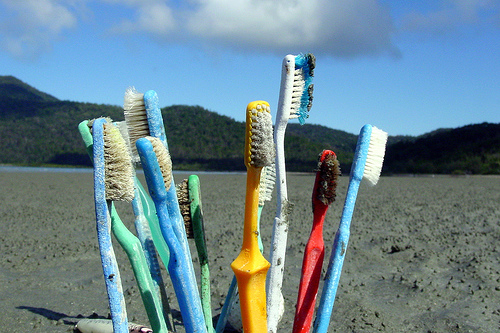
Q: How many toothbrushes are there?
A: Ten.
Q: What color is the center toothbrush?
A: Yellow.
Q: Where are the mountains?
A: The background.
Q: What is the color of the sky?
A: Blue.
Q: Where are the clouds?
A: The sky.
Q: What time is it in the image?
A: Daytime.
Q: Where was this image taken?
A: At a beach.